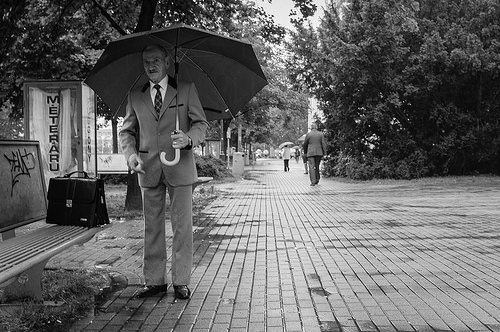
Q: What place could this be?
A: It is a sidewalk.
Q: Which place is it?
A: It is a sidewalk.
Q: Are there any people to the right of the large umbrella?
A: Yes, there is a person to the right of the umbrella.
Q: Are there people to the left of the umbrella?
A: No, the person is to the right of the umbrella.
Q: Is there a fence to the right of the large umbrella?
A: No, there is a person to the right of the umbrella.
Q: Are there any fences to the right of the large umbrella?
A: No, there is a person to the right of the umbrella.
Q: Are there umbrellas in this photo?
A: Yes, there is an umbrella.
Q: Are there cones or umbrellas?
A: Yes, there is an umbrella.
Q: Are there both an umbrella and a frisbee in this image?
A: No, there is an umbrella but no frisbees.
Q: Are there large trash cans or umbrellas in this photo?
A: Yes, there is a large umbrella.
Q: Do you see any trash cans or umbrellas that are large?
A: Yes, the umbrella is large.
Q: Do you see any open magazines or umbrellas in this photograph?
A: Yes, there is an open umbrella.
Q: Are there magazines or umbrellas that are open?
A: Yes, the umbrella is open.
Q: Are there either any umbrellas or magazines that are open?
A: Yes, the umbrella is open.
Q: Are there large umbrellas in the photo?
A: Yes, there is a large umbrella.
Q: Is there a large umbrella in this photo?
A: Yes, there is a large umbrella.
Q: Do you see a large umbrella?
A: Yes, there is a large umbrella.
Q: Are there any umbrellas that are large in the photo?
A: Yes, there is a large umbrella.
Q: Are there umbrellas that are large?
A: Yes, there is an umbrella that is large.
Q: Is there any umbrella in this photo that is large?
A: Yes, there is an umbrella that is large.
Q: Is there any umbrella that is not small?
A: Yes, there is a large umbrella.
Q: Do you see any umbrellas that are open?
A: Yes, there is an open umbrella.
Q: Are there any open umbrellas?
A: Yes, there is an open umbrella.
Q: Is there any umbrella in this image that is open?
A: Yes, there is an umbrella that is open.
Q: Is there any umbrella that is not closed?
A: Yes, there is a open umbrella.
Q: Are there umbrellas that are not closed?
A: Yes, there is a open umbrella.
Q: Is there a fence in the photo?
A: No, there are no fences.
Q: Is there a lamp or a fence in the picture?
A: No, there are no fences or lamps.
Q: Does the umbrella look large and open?
A: Yes, the umbrella is large and open.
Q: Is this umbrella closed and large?
A: No, the umbrella is large but open.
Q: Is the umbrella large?
A: Yes, the umbrella is large.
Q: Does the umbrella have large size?
A: Yes, the umbrella is large.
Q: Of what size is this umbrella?
A: The umbrella is large.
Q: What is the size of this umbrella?
A: The umbrella is large.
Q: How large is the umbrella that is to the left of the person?
A: The umbrella is large.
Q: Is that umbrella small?
A: No, the umbrella is large.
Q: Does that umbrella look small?
A: No, the umbrella is large.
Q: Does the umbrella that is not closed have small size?
A: No, the umbrella is large.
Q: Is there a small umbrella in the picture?
A: No, there is an umbrella but it is large.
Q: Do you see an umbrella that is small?
A: No, there is an umbrella but it is large.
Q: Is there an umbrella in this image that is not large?
A: No, there is an umbrella but it is large.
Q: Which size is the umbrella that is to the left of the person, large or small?
A: The umbrella is large.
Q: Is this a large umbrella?
A: Yes, this is a large umbrella.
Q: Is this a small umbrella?
A: No, this is a large umbrella.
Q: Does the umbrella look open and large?
A: Yes, the umbrella is open and large.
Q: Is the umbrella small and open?
A: No, the umbrella is open but large.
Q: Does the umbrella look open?
A: Yes, the umbrella is open.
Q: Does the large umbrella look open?
A: Yes, the umbrella is open.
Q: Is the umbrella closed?
A: No, the umbrella is open.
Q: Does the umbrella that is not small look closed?
A: No, the umbrella is open.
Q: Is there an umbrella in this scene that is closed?
A: No, there is an umbrella but it is open.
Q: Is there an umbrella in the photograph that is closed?
A: No, there is an umbrella but it is open.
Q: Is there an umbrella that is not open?
A: No, there is an umbrella but it is open.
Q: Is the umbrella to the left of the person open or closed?
A: The umbrella is open.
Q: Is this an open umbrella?
A: Yes, this is an open umbrella.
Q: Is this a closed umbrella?
A: No, this is an open umbrella.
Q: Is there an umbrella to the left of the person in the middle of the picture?
A: Yes, there is an umbrella to the left of the person.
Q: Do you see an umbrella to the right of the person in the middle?
A: No, the umbrella is to the left of the person.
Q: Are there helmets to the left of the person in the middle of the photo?
A: No, there is an umbrella to the left of the person.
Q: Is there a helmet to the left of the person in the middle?
A: No, there is an umbrella to the left of the person.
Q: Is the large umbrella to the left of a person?
A: Yes, the umbrella is to the left of a person.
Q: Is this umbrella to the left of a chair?
A: No, the umbrella is to the left of a person.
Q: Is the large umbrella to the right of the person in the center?
A: No, the umbrella is to the left of the person.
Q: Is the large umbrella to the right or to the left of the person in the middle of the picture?
A: The umbrella is to the left of the person.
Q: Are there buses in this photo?
A: No, there are no buses.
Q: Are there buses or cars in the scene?
A: No, there are no buses or cars.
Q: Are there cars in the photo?
A: No, there are no cars.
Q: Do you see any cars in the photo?
A: No, there are no cars.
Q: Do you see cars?
A: No, there are no cars.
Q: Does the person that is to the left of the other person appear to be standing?
A: Yes, the person is standing.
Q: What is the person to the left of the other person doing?
A: The person is standing.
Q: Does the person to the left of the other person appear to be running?
A: No, the person is standing.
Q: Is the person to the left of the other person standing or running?
A: The person is standing.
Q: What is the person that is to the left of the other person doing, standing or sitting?
A: The person is standing.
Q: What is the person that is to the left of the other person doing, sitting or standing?
A: The person is standing.